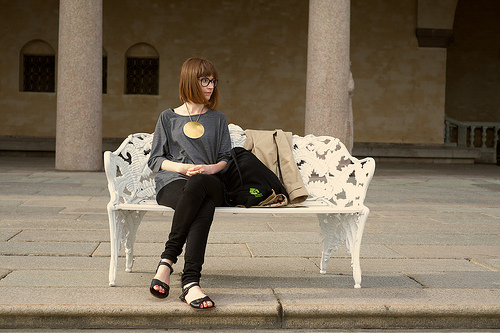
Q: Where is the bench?
A: Sidewalk.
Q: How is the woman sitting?
A: Legs crossed.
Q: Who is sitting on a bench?
A: A woman.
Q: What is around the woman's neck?
A: A necklace.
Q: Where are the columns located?
A: Behind the bench.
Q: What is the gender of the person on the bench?
A: Female.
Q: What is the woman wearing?
A: A grey shirt.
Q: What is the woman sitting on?
A: A white bench.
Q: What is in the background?
A: Windows.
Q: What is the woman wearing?
A: Black pants.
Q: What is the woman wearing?
A: Black sandals.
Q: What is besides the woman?
A: A tan coat.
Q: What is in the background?
A: A beige building.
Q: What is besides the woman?
A: Black clothing.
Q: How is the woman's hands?
A: They are crossed.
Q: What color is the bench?
A: White.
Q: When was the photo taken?
A: Daytime.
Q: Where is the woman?
A: On the bench.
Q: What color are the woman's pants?
A: Black.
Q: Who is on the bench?
A: The woman.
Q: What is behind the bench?
A: Two columns.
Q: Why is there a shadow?
A: It is sunny.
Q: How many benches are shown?
A: One.